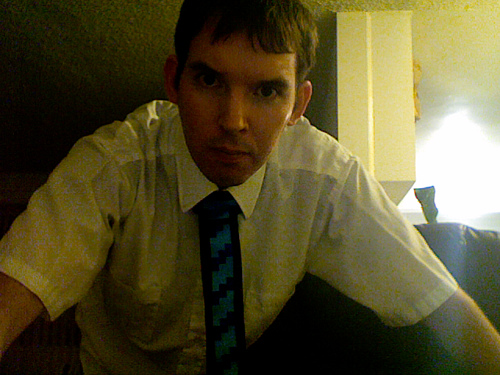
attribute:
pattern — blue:
[213, 211, 242, 353]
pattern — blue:
[205, 217, 235, 340]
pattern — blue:
[202, 222, 241, 363]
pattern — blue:
[197, 209, 228, 345]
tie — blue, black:
[181, 187, 247, 373]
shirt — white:
[9, 99, 459, 357]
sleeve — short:
[309, 158, 459, 333]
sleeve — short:
[4, 131, 121, 321]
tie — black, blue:
[199, 189, 254, 341]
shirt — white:
[254, 174, 394, 305]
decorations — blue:
[202, 210, 262, 350]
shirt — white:
[74, 129, 384, 355]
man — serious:
[113, 10, 363, 233]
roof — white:
[2, 0, 146, 83]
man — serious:
[141, 13, 328, 214]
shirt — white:
[73, 156, 199, 351]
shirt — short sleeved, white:
[37, 140, 229, 363]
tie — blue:
[202, 194, 252, 373]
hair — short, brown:
[196, 0, 286, 49]